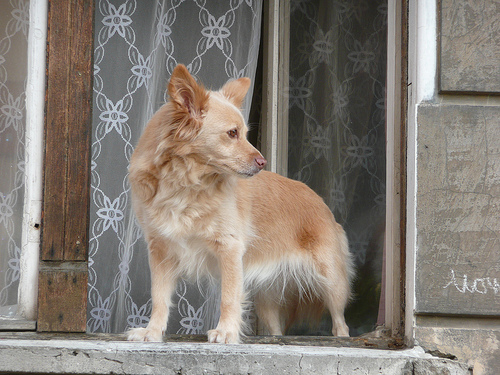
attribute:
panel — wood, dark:
[39, 8, 89, 329]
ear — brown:
[168, 55, 190, 108]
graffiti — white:
[464, 264, 498, 329]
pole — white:
[9, 63, 59, 303]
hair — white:
[257, 232, 318, 311]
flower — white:
[105, 6, 133, 40]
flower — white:
[94, 191, 124, 232]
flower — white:
[101, 195, 140, 248]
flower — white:
[200, 12, 226, 55]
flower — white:
[88, 290, 128, 327]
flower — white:
[184, 300, 210, 339]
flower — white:
[96, 93, 138, 134]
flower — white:
[124, 303, 143, 327]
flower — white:
[198, 16, 223, 48]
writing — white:
[446, 270, 484, 294]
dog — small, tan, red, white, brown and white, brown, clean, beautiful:
[122, 65, 358, 349]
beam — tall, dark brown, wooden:
[36, 4, 103, 336]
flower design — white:
[103, 98, 130, 132]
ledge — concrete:
[0, 333, 428, 372]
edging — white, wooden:
[19, 0, 39, 319]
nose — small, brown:
[255, 157, 265, 167]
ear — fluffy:
[169, 63, 199, 110]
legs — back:
[257, 287, 356, 339]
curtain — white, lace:
[95, 7, 243, 331]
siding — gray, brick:
[414, 19, 481, 369]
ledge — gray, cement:
[6, 328, 414, 372]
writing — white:
[449, 268, 484, 304]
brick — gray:
[418, 100, 484, 310]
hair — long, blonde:
[144, 158, 329, 301]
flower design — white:
[92, 93, 132, 140]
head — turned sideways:
[180, 88, 270, 179]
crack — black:
[331, 347, 343, 373]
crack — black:
[111, 344, 234, 354]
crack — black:
[295, 344, 308, 373]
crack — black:
[333, 350, 343, 373]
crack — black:
[407, 355, 420, 371]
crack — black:
[89, 344, 129, 373]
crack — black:
[64, 347, 94, 366]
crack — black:
[96, 350, 128, 373]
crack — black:
[295, 346, 305, 373]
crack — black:
[331, 346, 347, 371]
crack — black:
[63, 347, 91, 359]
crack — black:
[102, 354, 127, 370]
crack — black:
[102, 350, 126, 368]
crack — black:
[151, 357, 186, 373]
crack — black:
[157, 360, 184, 373]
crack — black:
[373, 351, 387, 372]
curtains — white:
[97, 14, 259, 317]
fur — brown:
[134, 115, 323, 264]